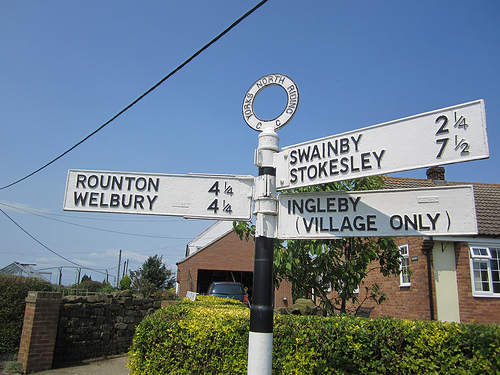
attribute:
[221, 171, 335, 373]
pole — black and white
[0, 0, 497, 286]
sky — blue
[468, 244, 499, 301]
window — white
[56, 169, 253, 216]
sign — one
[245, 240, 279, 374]
pole — white and black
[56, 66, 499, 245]
sign — street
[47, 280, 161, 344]
wall — grey stone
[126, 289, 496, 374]
fence — green and yellow, short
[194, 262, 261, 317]
gaarge door — open, opened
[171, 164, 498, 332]
building — brick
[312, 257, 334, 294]
window — white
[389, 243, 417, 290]
window — white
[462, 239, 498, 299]
window — white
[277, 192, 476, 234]
sign — Ingleby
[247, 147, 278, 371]
pole — white and black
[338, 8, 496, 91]
sky — blue, clear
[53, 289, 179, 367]
fence — stones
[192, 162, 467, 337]
building — bricks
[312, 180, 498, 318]
house — brick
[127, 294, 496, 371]
bushes — trimmed, green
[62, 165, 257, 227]
sign — Rounton and Welbury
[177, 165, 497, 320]
home — brick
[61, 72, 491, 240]
signs — white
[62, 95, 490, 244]
street signs — white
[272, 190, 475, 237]
sign — street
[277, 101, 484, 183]
sign — street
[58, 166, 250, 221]
sign — street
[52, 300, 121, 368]
retaining wall — brick